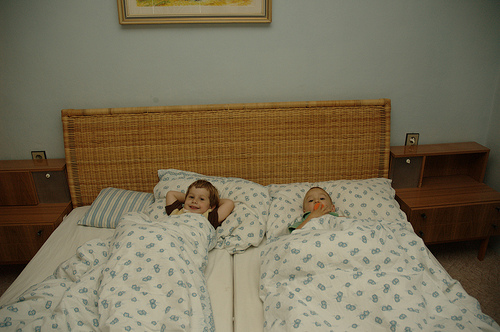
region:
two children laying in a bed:
[23, 62, 485, 323]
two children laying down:
[145, 166, 371, 312]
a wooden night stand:
[377, 94, 498, 243]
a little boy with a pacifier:
[265, 176, 356, 247]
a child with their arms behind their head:
[116, 155, 247, 322]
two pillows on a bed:
[144, 156, 406, 251]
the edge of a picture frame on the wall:
[103, 1, 291, 36]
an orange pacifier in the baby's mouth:
[312, 200, 325, 212]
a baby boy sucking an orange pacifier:
[285, 185, 345, 233]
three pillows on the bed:
[77, 167, 407, 254]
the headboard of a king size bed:
[60, 97, 391, 165]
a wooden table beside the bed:
[391, 140, 498, 260]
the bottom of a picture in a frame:
[117, 1, 272, 25]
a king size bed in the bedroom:
[0, 0, 498, 330]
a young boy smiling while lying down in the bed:
[0, 167, 231, 327]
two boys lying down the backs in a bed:
[0, 95, 497, 330]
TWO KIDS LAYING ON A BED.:
[43, 127, 460, 330]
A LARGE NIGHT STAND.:
[386, 131, 496, 249]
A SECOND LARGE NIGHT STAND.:
[5, 155, 78, 242]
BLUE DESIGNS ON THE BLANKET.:
[128, 248, 172, 292]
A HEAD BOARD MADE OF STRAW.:
[56, 98, 407, 194]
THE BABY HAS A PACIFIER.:
[286, 177, 342, 234]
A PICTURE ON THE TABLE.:
[394, 125, 424, 146]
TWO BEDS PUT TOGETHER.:
[219, 264, 259, 321]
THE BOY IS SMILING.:
[153, 168, 235, 232]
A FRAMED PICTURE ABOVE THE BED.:
[111, 0, 274, 27]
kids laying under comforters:
[121, 168, 383, 275]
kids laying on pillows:
[176, 166, 426, 256]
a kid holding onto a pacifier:
[293, 185, 339, 218]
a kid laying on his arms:
[156, 174, 232, 224]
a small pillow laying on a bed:
[83, 171, 147, 221]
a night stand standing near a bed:
[1, 144, 66, 221]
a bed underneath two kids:
[68, 177, 435, 330]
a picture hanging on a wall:
[80, 1, 298, 32]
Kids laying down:
[153, 183, 364, 240]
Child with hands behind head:
[155, 170, 239, 249]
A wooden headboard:
[57, 100, 393, 191]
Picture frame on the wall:
[117, 3, 277, 29]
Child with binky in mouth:
[282, 187, 352, 240]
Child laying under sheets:
[278, 183, 354, 231]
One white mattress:
[1, 198, 234, 330]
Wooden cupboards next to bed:
[4, 161, 69, 256]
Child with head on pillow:
[154, 182, 235, 239]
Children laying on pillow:
[151, 178, 346, 233]